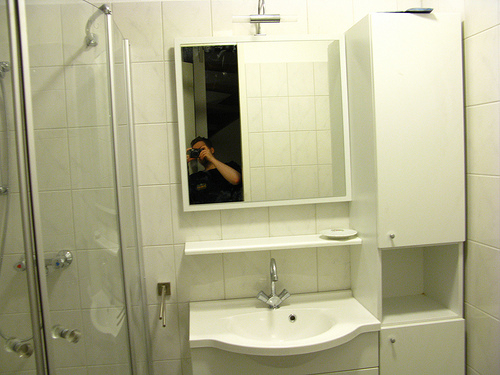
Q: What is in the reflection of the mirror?
A: The man with a camera.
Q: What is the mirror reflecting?
A: A man.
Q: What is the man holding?
A: A camera.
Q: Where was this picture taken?
A: A bathroom.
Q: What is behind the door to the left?
A: A shower.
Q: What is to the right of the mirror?
A: A cabinet.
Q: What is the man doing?
A: Taking a picture of the bathroom.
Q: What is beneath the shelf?
A: A sink.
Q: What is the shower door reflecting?
A: The shelf and sink.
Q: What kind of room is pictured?
A: A bathroom.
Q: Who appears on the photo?
A: A man.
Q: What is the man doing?
A: Taking a photograph.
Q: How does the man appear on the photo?
A: Reflected on the mirror.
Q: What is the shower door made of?
A: Glass.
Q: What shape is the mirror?
A: Rectangular.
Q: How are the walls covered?
A: With white tiles.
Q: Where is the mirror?
A: Above the sink.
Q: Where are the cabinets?
A: To the right of the sink.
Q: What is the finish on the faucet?
A: Chrome.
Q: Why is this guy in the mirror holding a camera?
A: He is taking a selfie.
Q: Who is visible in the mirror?
A: A man.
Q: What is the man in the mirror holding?
A: A camera.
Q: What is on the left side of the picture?
A: Shower.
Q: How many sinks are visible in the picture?
A: One.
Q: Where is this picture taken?
A: Bathroom.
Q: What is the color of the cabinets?
A: White.